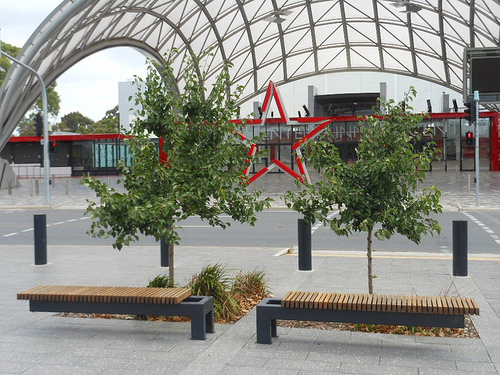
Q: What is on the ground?
A: The bench.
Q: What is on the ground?
A: Bench.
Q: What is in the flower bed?
A: The tree.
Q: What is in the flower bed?
A: The tree.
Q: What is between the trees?
A: The red star.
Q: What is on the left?
A: The bench.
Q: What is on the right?
A: The bench.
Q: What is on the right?
A: The tree.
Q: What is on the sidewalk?
A: Black poles.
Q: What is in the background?
A: The building.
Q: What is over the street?
A: The arched design.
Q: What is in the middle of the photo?
A: The street.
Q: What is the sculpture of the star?
A: Red.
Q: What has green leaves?
A: Two trees.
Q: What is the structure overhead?
A: Metal and glass.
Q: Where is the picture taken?
A: A sidewalk.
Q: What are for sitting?
A: Benches.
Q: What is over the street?
A: A metal dome.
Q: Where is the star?
A: Suspended in air.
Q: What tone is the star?
A: Red.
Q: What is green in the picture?
A: Trees.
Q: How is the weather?
A: Overcast.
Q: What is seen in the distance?
A: City skyscrapers.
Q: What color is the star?
A: Red.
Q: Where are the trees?
A: Behind benches.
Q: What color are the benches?
A: Brown.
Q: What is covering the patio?
A: Dome.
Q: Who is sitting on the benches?
A: No one.